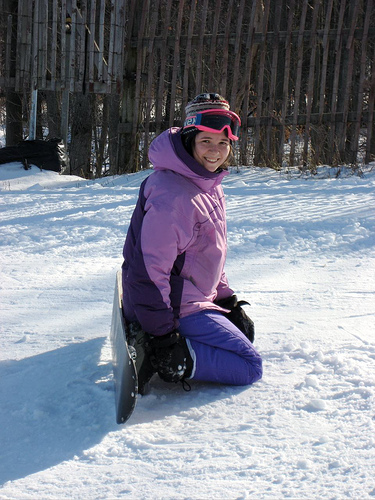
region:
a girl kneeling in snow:
[103, 94, 268, 424]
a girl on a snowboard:
[98, 86, 264, 439]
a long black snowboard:
[98, 268, 143, 431]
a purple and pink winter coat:
[117, 134, 233, 331]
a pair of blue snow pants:
[169, 304, 269, 392]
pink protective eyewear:
[182, 107, 246, 144]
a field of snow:
[4, 169, 368, 488]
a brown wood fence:
[6, 8, 368, 163]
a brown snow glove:
[216, 293, 254, 338]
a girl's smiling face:
[187, 128, 230, 170]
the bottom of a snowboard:
[105, 316, 139, 405]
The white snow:
[209, 417, 350, 496]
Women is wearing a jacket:
[150, 193, 228, 316]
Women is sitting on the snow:
[106, 148, 275, 389]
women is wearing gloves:
[229, 302, 263, 340]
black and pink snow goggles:
[192, 109, 248, 145]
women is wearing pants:
[193, 314, 259, 383]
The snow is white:
[285, 350, 374, 457]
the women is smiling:
[200, 147, 224, 165]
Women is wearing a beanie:
[192, 93, 228, 112]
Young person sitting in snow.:
[27, 56, 335, 469]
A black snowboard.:
[88, 268, 159, 434]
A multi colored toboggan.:
[171, 88, 253, 120]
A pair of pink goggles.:
[181, 104, 243, 141]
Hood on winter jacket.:
[141, 118, 244, 190]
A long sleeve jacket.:
[110, 117, 260, 334]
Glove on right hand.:
[145, 328, 202, 389]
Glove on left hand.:
[219, 288, 262, 341]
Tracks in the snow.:
[17, 393, 368, 484]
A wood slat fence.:
[6, 6, 359, 162]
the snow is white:
[172, 425, 224, 497]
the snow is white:
[208, 412, 277, 497]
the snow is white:
[185, 402, 241, 497]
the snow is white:
[207, 473, 234, 493]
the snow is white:
[242, 453, 276, 499]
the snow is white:
[207, 454, 253, 495]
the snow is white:
[222, 440, 258, 488]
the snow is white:
[205, 436, 237, 482]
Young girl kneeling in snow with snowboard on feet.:
[98, 93, 266, 425]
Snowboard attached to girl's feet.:
[101, 263, 150, 426]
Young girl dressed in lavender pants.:
[176, 301, 270, 397]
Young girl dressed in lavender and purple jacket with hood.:
[121, 123, 243, 335]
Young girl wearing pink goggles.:
[186, 105, 252, 141]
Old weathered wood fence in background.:
[247, 0, 373, 175]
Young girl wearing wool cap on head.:
[183, 90, 235, 113]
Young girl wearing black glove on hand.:
[147, 326, 193, 378]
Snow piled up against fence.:
[3, 158, 86, 210]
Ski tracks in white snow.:
[263, 254, 369, 357]